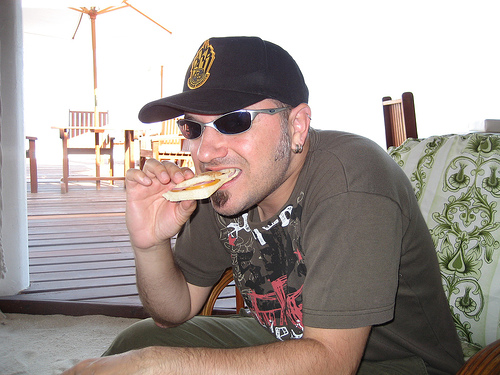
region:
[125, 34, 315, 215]
man with cap eating pizza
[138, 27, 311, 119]
baseball cap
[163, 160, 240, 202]
biting into pizza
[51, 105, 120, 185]
deck chair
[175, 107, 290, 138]
sunglasses with opaque tint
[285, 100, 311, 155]
ear with several piercings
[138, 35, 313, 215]
man with soul patch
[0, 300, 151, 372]
beige shag carpet with footprints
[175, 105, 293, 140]
silver designer sunglasses on face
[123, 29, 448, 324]
man wearing sunglasses indoors in front of porch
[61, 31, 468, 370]
man eating food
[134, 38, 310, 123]
black hat with a yellow symbol on front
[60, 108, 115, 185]
wooden chair on a deck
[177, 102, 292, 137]
silver sunglasses on the man's face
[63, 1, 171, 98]
pole of an ubrella blurred out by sun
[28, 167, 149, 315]
wooden deck with patio furniture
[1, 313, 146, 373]
sand on the ground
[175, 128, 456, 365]
brown shirt on the man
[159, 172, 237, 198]
food item in the man's mouth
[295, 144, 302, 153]
earring in the man's left ear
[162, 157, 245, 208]
piece of food going into a mans mouth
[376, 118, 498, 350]
green and white blanket design on the back of a chair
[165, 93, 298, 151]
man wearing black and silver sun glasses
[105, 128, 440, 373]
man wearing a brown shirt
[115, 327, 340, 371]
a man's arm hair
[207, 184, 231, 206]
brown goatee on a man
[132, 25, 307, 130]
a man wearing a black hat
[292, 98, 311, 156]
earrings on a man's ear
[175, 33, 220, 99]
yellow logo on a black hat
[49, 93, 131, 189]
wooden chair on the deck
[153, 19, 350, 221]
Black hat on the man.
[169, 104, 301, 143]
Sunglasses on the man.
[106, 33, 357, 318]
Man eating food.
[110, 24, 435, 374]
Man sitting down and eating food.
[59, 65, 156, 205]
Bench on the deck.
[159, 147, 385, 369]
Logo on the shirt.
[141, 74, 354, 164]
Silver sunglasses on the man.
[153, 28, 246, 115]
Logo on the black hat.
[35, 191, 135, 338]
Deck in the background.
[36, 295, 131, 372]
Sand by the deck.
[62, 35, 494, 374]
Man sitting on a chair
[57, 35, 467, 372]
Man sitting and eating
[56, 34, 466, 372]
Man wearing a black baseball cap and silver sunglasses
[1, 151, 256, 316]
Outdoor wood plank deck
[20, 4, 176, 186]
Large table umbrella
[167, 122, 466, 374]
Gray graphic t-shirt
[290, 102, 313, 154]
Three earring in an ear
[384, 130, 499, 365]
Green pattern on a white back cushion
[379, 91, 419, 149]
Wood back of a chair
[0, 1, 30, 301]
Painted white support beam